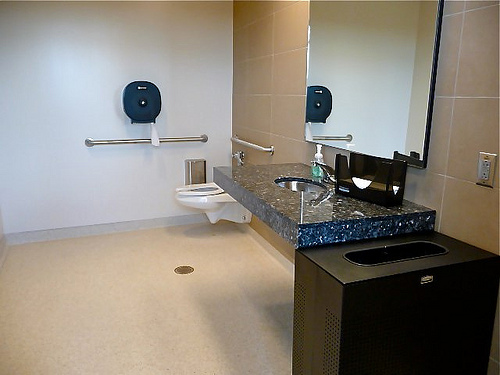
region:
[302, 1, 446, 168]
reflective mirror in restroom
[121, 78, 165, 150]
black plastic toilet paper holder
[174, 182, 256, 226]
white ceramic toilet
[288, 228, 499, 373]
black trashcan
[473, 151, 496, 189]
electrical outlet on wall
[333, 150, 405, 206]
black plastic paper towel holder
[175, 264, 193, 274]
circular drain on floor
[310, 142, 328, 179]
soap dispense on top of sink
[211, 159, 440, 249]
black marble sink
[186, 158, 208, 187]
silver metal trash dispenser next to toilet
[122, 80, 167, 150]
See Through Black Toilet Paper Holder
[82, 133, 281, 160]
Shiny Metal Helping Bars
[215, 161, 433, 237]
Black Speckled Granite Counter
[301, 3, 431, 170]
Sparkling Clean Mirror On The Wall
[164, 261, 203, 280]
Bathroom Floor Drain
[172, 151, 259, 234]
White Toliet Attached to the wall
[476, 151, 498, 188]
Wall Outlit with a Beige cover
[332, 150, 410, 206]
Large black napkin holder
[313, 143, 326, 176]
Hand pump disinfecting soap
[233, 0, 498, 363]
Large Beige Tiles On The Back Wall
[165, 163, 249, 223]
white toilet in bathroom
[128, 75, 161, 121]
black toilet paper dispenser on wall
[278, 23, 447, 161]
large square mirror in bathroom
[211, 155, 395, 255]
black granite counter top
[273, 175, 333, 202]
silver sink cut into granite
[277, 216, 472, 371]
black cabinet on right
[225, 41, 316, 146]
tan tiles on wall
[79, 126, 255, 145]
metal rail on wall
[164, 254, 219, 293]
round drain on ground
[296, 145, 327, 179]
small soap bottle on sink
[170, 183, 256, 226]
White commode inside restroom.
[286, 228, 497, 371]
Black trash bin inside restroom.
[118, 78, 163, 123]
Toilet paper holder mounted on wall.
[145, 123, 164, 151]
Toilet paper hanging out of holder.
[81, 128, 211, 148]
Support bar on side of commode.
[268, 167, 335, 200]
Sink on top of counter.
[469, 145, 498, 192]
Electrical outlet mounted on wall.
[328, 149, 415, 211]
Holder for paper hand towels.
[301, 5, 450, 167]
Mirror mounted on restroom wall.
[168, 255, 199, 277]
Drain on floor of restroom.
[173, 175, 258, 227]
A white toilet mounted on the wall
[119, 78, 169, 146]
A paper towel dispenser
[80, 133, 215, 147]
A metal handrail mounted on the wall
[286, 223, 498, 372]
A large black waste bin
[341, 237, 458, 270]
The opening on top of the waste bin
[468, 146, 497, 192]
A power outlet on the wall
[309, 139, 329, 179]
A bottle of soap on the counter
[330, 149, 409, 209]
A black paper towel holder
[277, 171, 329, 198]
A small chrome sink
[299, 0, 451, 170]
A frameless mirror on the wall